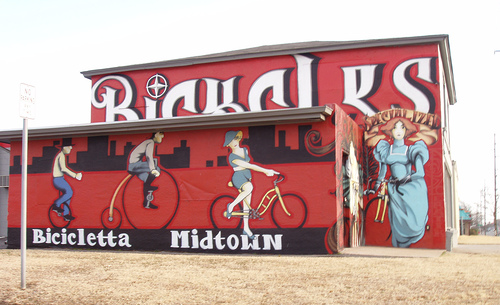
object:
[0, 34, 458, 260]
house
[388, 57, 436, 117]
word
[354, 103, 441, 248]
picture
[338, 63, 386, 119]
letter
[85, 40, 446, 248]
wall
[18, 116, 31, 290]
pole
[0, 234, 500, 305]
grass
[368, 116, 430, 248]
woman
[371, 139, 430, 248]
dress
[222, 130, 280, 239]
woman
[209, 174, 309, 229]
bike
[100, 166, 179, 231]
bike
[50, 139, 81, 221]
man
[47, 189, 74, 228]
unicycle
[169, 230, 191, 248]
word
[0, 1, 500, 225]
sky